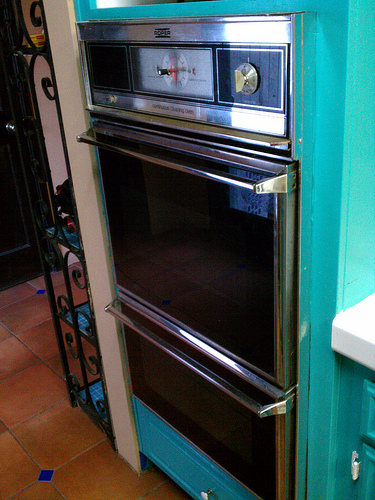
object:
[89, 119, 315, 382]
oven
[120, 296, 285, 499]
broiler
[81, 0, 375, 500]
wall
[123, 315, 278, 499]
door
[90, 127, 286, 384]
door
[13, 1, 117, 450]
shelf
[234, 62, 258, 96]
knob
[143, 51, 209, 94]
clock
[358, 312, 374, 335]
white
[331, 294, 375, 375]
counter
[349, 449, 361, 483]
hinge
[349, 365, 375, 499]
cabinet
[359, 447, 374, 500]
door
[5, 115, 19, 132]
knob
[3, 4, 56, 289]
door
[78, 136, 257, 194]
handle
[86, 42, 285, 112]
controls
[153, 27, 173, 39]
name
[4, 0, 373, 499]
kitchen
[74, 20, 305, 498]
unit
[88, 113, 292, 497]
ovens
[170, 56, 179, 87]
time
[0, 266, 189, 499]
flooring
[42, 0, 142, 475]
corner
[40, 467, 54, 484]
tile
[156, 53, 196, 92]
timer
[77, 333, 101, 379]
spirals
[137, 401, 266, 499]
drawer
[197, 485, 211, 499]
handle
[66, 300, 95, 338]
tiles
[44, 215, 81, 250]
tiles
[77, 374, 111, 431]
tiles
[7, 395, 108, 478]
tiles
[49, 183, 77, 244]
items